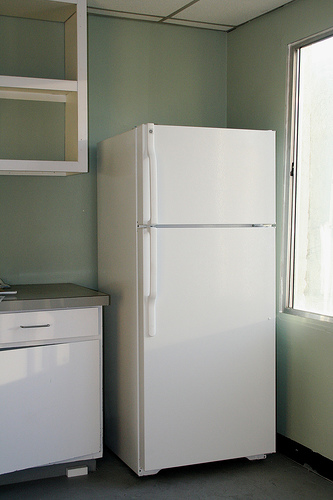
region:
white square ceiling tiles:
[91, 1, 292, 30]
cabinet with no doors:
[0, 1, 87, 174]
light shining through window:
[285, 34, 332, 315]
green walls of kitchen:
[0, 0, 332, 465]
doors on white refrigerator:
[98, 123, 276, 474]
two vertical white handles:
[142, 123, 157, 336]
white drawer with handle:
[0, 307, 100, 342]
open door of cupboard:
[0, 337, 102, 474]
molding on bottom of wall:
[276, 434, 332, 480]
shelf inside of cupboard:
[0, 77, 76, 99]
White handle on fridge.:
[140, 272, 175, 340]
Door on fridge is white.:
[159, 306, 219, 411]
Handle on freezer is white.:
[142, 167, 174, 212]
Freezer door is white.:
[167, 159, 236, 207]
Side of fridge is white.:
[110, 383, 137, 425]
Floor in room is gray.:
[226, 474, 269, 497]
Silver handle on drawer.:
[16, 321, 81, 343]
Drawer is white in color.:
[4, 316, 108, 339]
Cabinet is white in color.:
[24, 363, 78, 425]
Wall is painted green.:
[20, 197, 71, 240]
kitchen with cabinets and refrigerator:
[6, 5, 315, 482]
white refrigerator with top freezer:
[94, 115, 284, 469]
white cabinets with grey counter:
[0, 286, 114, 483]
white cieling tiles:
[83, 0, 306, 33]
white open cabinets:
[0, 0, 95, 180]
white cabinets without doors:
[0, 1, 96, 187]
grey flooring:
[0, 452, 329, 494]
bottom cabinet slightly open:
[3, 344, 100, 472]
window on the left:
[280, 27, 327, 324]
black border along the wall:
[279, 430, 330, 477]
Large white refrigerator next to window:
[95, 121, 276, 476]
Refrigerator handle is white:
[145, 121, 159, 226]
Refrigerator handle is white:
[144, 226, 158, 335]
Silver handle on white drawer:
[18, 323, 51, 329]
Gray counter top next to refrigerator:
[0, 284, 114, 312]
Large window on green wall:
[275, 26, 331, 325]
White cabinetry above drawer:
[0, 0, 92, 178]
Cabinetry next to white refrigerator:
[0, 0, 92, 177]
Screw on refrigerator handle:
[147, 128, 152, 134]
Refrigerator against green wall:
[96, 121, 282, 476]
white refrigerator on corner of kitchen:
[94, 118, 279, 475]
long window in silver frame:
[279, 28, 328, 314]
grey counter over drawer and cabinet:
[0, 276, 101, 478]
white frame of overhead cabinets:
[0, 2, 83, 173]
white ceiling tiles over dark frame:
[85, 0, 284, 29]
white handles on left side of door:
[140, 119, 155, 333]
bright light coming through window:
[283, 36, 326, 312]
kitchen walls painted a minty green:
[0, 0, 326, 455]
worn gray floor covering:
[3, 437, 327, 494]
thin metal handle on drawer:
[18, 321, 48, 327]